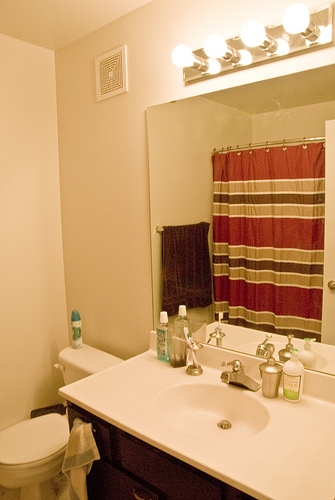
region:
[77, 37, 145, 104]
White vent on wall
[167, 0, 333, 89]
Light fixture over mirror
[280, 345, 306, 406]
Hand soap bottle on sink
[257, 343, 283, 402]
Silver hand soap bottle on seat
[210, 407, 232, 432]
Silver drain in sink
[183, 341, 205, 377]
Silver toothbrush holder on sink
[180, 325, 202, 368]
Toothbrush in toothbrush holder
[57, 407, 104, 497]
Tile hanging on front of sink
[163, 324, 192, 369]
Glass sitting on sink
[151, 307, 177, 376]
Mouthwash bottle on sink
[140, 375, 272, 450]
the sink in a bathroom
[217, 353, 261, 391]
the faucet in a bathroom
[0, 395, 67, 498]
the toilet in a bathroom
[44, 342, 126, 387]
the tank of a toilet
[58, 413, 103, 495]
a hand towel in a bathroom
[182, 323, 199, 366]
a toothbrush in a bathroom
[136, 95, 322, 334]
a mirror in a bathroom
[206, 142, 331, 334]
a shower curtain in a bathroom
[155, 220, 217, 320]
a brown towel in a bathroom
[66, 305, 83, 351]
a can of air freshener in a bathroom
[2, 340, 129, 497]
Toilet in the bathroom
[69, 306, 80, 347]
Air freshner on back of toilet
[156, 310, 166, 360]
Mouthwash on counter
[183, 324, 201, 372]
Toothbrush and holder on bathroom counter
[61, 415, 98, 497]
Towel hanging on drawer handle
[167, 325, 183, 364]
Glass on bathroom counter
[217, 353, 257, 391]
Faucet in bathroom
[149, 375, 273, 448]
Sink in bathroom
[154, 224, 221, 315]
Towel rack and towel hanging on the wall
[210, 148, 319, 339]
Shower curtain handing on rod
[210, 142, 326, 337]
A red, yellow, and brown striped shower curtain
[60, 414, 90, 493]
A white washcloth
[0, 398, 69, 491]
A white toilet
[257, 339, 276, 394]
A silver soap container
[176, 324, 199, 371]
A toothbrush holder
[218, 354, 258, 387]
The silver faucet of the sink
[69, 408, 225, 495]
Dark wooden cabinets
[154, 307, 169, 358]
Mouthwash on the sink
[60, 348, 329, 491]
The white sink counter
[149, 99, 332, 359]
A large bathroom mirror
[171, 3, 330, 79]
Multiple studio light bulbs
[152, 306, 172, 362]
mouth wash on counter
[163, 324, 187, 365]
Empty cup on counter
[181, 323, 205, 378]
Tooth brush holder on counter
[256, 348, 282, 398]
Silver soad dispenser on counter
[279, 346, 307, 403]
A bottle of lotion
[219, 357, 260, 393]
A steel sink fixture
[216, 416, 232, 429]
A silver sink drain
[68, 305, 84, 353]
Aerosol on toilet back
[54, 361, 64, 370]
Toilet lever flush handle